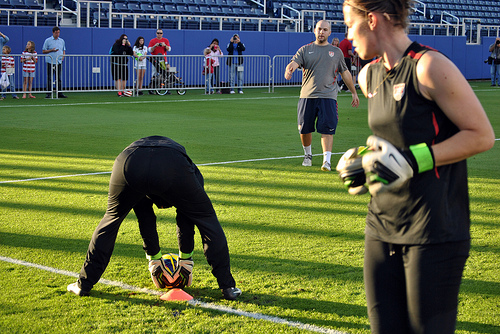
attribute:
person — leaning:
[59, 115, 241, 308]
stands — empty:
[5, 1, 499, 36]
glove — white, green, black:
[331, 139, 448, 199]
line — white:
[3, 252, 342, 332]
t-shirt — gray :
[297, 40, 343, 102]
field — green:
[72, 98, 367, 266]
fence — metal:
[1, 49, 301, 113]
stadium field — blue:
[0, 77, 498, 332]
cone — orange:
[156, 286, 195, 302]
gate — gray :
[54, 50, 131, 95]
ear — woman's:
[364, 11, 377, 32]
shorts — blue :
[292, 97, 357, 129]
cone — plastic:
[158, 284, 194, 301]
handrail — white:
[436, 7, 463, 37]